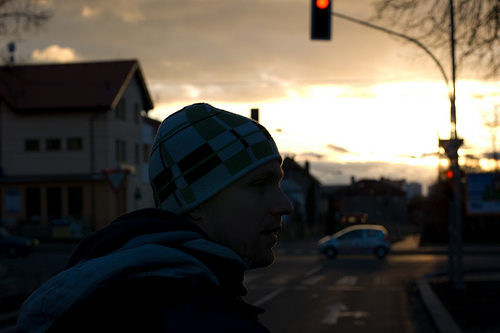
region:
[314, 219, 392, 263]
large light color vehicle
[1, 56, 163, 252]
2 story building with red roof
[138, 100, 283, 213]
a knit cap with multicolor design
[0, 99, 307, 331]
man wearing knit cap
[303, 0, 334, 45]
a red traffic light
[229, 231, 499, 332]
road in the middle of town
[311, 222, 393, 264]
A car is crossing the street.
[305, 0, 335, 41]
The traffic light is red.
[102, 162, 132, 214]
A yeild sign is by the homes.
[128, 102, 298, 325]
The man is wearing a hat.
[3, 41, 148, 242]
Apartments are in the background.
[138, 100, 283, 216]
The hat is a beanie.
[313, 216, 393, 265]
The car is small and silver.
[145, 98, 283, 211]
The hat is black and white.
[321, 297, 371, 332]
There are arrows on the road.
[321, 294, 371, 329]
The arrows on the road are white.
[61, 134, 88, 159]
Small window on a building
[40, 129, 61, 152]
Small window on a building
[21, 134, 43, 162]
Small window on a building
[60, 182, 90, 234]
Small window on a building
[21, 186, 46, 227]
Small window on a building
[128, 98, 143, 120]
Small window on a building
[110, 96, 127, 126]
Small window on a building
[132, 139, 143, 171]
Small window on a building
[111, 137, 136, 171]
Small window on a building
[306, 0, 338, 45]
street light at intersection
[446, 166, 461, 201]
red street light on pole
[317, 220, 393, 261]
small silver car under light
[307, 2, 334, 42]
red street light at intersection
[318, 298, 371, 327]
white arrow painted on street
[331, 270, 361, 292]
cross walk lines on street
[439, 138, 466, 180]
street sign above red light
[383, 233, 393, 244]
red tail light of silver car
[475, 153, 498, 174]
sun setting in background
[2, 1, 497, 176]
cloud cover in sky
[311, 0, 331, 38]
red glow of traffic light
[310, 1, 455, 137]
curved pole of traffic light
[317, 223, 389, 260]
side of car on street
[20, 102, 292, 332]
profile of man in hat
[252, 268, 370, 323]
white lines and arrows on street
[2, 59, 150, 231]
curved roof of house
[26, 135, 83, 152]
three square windows of building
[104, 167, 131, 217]
triangle sign on pole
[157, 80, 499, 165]
sunlight in sky on horizon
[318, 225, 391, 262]
a silver car in the intersection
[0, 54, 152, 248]
a brown house in the back ground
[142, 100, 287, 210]
a black and white cap